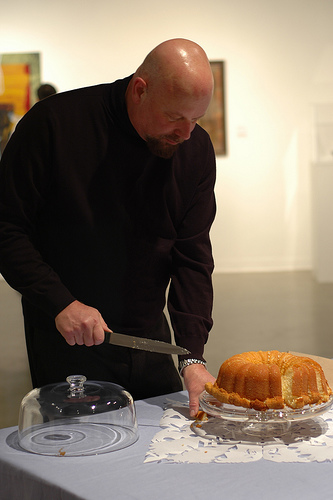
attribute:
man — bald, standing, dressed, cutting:
[1, 37, 221, 422]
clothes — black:
[1, 74, 217, 425]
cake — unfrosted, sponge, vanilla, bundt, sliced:
[203, 349, 332, 412]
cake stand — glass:
[198, 390, 332, 435]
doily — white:
[145, 396, 333, 465]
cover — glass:
[18, 374, 139, 456]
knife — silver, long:
[104, 331, 190, 357]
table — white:
[1, 381, 331, 498]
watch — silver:
[178, 358, 206, 374]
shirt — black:
[2, 71, 217, 365]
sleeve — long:
[167, 130, 216, 365]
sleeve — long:
[1, 97, 80, 322]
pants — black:
[21, 295, 184, 423]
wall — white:
[1, 1, 333, 273]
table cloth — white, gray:
[1, 374, 333, 499]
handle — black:
[103, 331, 113, 343]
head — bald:
[124, 37, 213, 158]